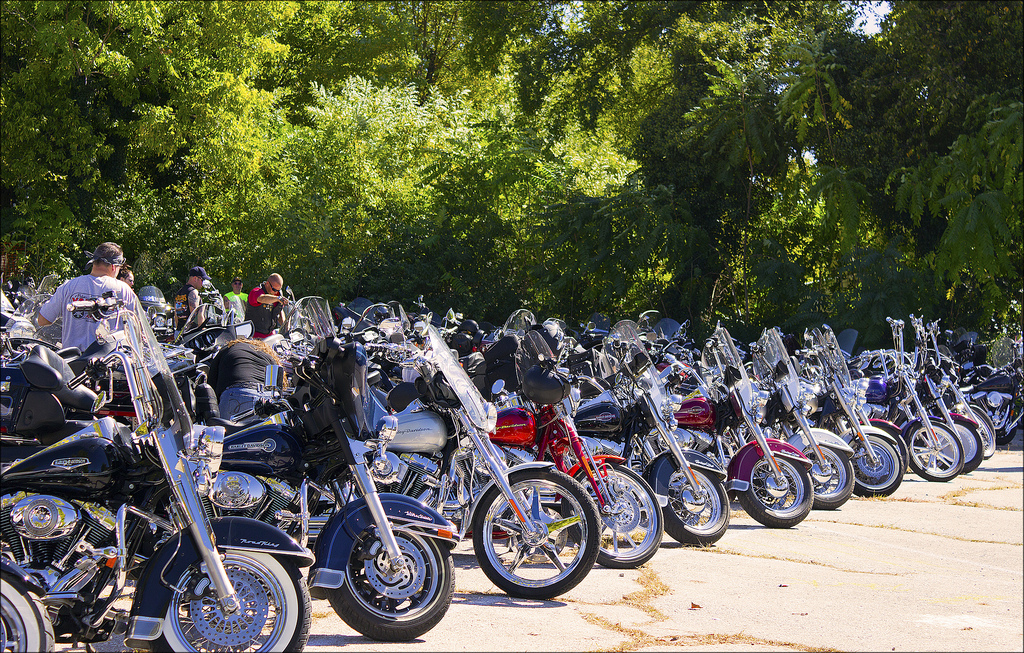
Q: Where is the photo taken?
A: In a parking lot.